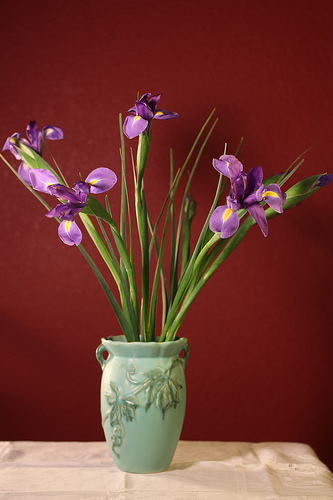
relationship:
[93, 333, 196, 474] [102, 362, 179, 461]
vase has design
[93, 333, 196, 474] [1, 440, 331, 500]
vase sitting on table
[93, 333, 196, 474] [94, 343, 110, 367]
vase has handle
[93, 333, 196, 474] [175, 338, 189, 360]
vase has handle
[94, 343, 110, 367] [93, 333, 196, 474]
handle on vase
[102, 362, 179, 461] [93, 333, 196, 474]
design on vase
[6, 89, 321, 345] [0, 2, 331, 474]
bouquet in front of wall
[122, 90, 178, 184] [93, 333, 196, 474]
flower bloom inside vase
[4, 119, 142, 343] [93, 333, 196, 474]
flower inside vase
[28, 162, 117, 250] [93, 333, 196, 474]
flower bloom inside vase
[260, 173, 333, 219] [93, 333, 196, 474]
flower inside vase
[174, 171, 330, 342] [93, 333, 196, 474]
flower inside vase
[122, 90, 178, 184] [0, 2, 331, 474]
flower bloom in front of wall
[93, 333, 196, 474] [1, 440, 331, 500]
vase on table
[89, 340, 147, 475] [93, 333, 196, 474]
light reflection off vase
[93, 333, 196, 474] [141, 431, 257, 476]
vase casting shadow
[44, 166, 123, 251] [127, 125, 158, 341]
flower bloom on flower stem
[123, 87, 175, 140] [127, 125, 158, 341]
flower bloom on flower stem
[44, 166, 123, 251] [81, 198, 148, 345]
flower bloom on flower stem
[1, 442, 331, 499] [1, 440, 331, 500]
table cloth covers table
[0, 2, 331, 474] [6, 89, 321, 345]
wall behind bouquet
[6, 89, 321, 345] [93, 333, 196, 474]
bouquet inside vase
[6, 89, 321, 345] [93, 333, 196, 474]
bouquet in vase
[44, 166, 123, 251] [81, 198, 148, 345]
flower bloom has flower stem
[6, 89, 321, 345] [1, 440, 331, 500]
bouquet on top of table